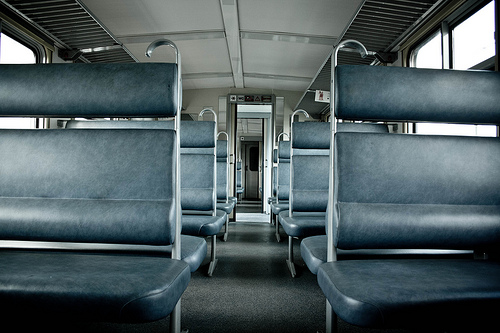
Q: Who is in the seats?
A: No one.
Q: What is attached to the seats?
A: Handles.